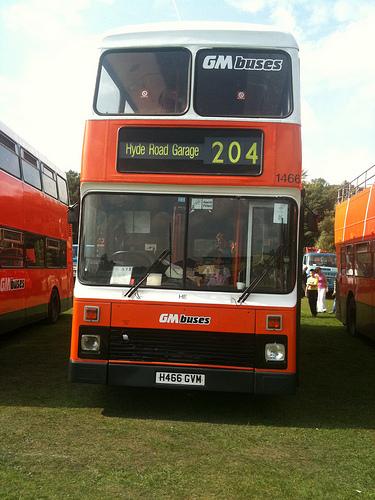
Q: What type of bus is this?
A: Double decker.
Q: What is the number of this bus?
A: 204.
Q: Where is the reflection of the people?
A: In the windshield.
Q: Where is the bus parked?
A: On grass.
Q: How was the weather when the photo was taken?
A: Sunshine.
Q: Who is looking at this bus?
A: The photographer.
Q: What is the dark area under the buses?
A: Shadow.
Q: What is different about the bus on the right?
A: It is an open-top double-decker.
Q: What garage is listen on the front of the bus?
A: Hyde Road Garage.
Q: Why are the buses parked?
A: They are not being used for a tour, currently.